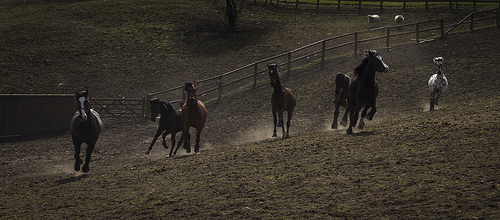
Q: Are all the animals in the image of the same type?
A: No, they are sheep and horses.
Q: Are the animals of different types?
A: Yes, they are sheep and horses.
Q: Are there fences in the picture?
A: Yes, there is a fence.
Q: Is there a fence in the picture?
A: Yes, there is a fence.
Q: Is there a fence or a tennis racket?
A: Yes, there is a fence.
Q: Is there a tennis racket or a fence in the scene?
A: Yes, there is a fence.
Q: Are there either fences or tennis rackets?
A: Yes, there is a fence.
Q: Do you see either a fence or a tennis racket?
A: Yes, there is a fence.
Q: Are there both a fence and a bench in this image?
A: No, there is a fence but no benches.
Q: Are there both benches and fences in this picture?
A: No, there is a fence but no benches.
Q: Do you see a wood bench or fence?
A: Yes, there is a wood fence.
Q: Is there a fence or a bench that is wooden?
A: Yes, the fence is wooden.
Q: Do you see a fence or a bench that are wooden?
A: Yes, the fence is wooden.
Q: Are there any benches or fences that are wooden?
A: Yes, the fence is wooden.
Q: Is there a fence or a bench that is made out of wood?
A: Yes, the fence is made of wood.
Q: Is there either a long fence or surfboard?
A: Yes, there is a long fence.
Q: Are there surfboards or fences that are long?
A: Yes, the fence is long.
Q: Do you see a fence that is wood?
A: Yes, there is a wood fence.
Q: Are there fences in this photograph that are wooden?
A: Yes, there is a fence that is wooden.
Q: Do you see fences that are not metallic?
A: Yes, there is a wooden fence.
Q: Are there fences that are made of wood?
A: Yes, there is a fence that is made of wood.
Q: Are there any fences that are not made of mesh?
A: Yes, there is a fence that is made of wood.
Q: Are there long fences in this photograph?
A: Yes, there is a long fence.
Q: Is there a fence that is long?
A: Yes, there is a fence that is long.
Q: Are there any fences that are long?
A: Yes, there is a fence that is long.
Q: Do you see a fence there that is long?
A: Yes, there is a fence that is long.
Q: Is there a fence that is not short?
A: Yes, there is a long fence.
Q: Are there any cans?
A: No, there are no cans.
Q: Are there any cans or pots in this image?
A: No, there are no cans or pots.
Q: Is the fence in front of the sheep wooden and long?
A: Yes, the fence is wooden and long.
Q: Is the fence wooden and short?
A: No, the fence is wooden but long.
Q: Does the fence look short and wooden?
A: No, the fence is wooden but long.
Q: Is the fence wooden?
A: Yes, the fence is wooden.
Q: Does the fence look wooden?
A: Yes, the fence is wooden.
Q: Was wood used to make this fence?
A: Yes, the fence is made of wood.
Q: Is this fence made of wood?
A: Yes, the fence is made of wood.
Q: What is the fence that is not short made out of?
A: The fence is made of wood.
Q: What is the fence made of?
A: The fence is made of wood.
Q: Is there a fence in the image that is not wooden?
A: No, there is a fence but it is wooden.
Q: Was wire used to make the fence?
A: No, the fence is made of wood.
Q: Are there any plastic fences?
A: No, there is a fence but it is made of wood.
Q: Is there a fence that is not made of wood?
A: No, there is a fence but it is made of wood.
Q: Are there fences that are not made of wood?
A: No, there is a fence but it is made of wood.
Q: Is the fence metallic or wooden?
A: The fence is wooden.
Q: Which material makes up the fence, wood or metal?
A: The fence is made of wood.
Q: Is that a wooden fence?
A: Yes, that is a wooden fence.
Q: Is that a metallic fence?
A: No, that is a wooden fence.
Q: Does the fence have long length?
A: Yes, the fence is long.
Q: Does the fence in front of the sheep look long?
A: Yes, the fence is long.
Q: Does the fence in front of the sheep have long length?
A: Yes, the fence is long.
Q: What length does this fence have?
A: The fence has long length.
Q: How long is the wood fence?
A: The fence is long.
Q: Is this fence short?
A: No, the fence is long.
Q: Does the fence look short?
A: No, the fence is long.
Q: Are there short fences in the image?
A: No, there is a fence but it is long.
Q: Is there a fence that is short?
A: No, there is a fence but it is long.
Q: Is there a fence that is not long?
A: No, there is a fence but it is long.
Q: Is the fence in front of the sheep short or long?
A: The fence is long.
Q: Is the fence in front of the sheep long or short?
A: The fence is long.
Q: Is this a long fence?
A: Yes, this is a long fence.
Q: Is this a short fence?
A: No, this is a long fence.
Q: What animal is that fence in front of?
A: The fence is in front of the sheep.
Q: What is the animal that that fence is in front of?
A: The animal is a sheep.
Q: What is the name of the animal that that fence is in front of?
A: The animal is a sheep.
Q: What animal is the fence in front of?
A: The fence is in front of the sheep.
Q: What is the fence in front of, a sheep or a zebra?
A: The fence is in front of a sheep.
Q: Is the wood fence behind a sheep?
A: No, the fence is in front of a sheep.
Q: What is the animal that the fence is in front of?
A: The animal is a sheep.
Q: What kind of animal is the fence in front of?
A: The fence is in front of the sheep.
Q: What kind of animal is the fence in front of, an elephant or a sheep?
A: The fence is in front of a sheep.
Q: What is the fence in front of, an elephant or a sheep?
A: The fence is in front of a sheep.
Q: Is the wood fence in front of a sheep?
A: Yes, the fence is in front of a sheep.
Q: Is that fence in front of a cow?
A: No, the fence is in front of a sheep.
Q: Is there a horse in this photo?
A: Yes, there is a horse.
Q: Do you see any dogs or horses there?
A: Yes, there is a horse.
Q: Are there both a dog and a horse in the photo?
A: No, there is a horse but no dogs.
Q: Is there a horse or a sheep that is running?
A: Yes, the horse is running.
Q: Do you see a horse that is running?
A: Yes, there is a horse that is running.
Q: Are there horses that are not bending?
A: Yes, there is a horse that is running.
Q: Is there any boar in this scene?
A: No, there are no boars.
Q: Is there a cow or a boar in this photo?
A: No, there are no boars or cows.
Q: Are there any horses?
A: Yes, there is a horse.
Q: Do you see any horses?
A: Yes, there is a horse.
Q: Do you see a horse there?
A: Yes, there is a horse.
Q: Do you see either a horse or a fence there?
A: Yes, there is a horse.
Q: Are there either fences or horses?
A: Yes, there is a horse.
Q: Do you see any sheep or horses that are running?
A: Yes, the horse is running.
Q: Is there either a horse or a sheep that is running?
A: Yes, the horse is running.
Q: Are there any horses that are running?
A: Yes, there is a horse that is running.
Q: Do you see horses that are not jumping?
A: Yes, there is a horse that is running .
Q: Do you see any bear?
A: No, there are no bears.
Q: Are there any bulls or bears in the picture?
A: No, there are no bears or bulls.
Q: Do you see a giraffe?
A: No, there are no giraffes.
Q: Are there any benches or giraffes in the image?
A: No, there are no giraffes or benches.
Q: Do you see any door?
A: Yes, there is a door.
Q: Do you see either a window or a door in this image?
A: Yes, there is a door.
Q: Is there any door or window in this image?
A: Yes, there is a door.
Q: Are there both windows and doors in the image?
A: No, there is a door but no windows.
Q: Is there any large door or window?
A: Yes, there is a large door.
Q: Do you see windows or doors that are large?
A: Yes, the door is large.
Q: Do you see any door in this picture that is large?
A: Yes, there is a large door.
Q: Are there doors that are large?
A: Yes, there is a door that is large.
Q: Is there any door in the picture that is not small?
A: Yes, there is a large door.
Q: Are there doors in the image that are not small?
A: Yes, there is a large door.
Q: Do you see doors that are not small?
A: Yes, there is a large door.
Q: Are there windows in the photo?
A: No, there are no windows.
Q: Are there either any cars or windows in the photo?
A: No, there are no windows or cars.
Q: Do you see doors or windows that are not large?
A: No, there is a door but it is large.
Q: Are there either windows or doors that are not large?
A: No, there is a door but it is large.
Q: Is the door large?
A: Yes, the door is large.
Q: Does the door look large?
A: Yes, the door is large.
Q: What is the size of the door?
A: The door is large.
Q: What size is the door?
A: The door is large.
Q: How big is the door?
A: The door is large.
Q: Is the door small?
A: No, the door is large.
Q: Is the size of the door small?
A: No, the door is large.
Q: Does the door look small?
A: No, the door is large.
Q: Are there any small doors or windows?
A: No, there is a door but it is large.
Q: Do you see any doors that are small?
A: No, there is a door but it is large.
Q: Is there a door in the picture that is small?
A: No, there is a door but it is large.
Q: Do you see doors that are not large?
A: No, there is a door but it is large.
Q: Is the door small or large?
A: The door is large.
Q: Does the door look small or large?
A: The door is large.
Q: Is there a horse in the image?
A: Yes, there is a horse.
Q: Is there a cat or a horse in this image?
A: Yes, there is a horse.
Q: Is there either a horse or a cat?
A: Yes, there is a horse.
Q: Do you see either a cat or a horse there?
A: Yes, there is a horse.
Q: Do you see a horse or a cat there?
A: Yes, there is a horse.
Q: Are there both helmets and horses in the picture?
A: No, there is a horse but no helmets.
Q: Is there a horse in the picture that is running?
A: Yes, there is a horse that is running.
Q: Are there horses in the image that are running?
A: Yes, there is a horse that is running.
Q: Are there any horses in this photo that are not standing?
A: Yes, there is a horse that is running.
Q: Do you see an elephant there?
A: No, there are no elephants.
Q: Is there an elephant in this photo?
A: No, there are no elephants.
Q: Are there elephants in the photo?
A: No, there are no elephants.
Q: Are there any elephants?
A: No, there are no elephants.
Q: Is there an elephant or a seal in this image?
A: No, there are no elephants or seals.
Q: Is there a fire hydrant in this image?
A: No, there are no fire hydrants.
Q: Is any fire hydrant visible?
A: No, there are no fire hydrants.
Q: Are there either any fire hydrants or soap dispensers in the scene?
A: No, there are no fire hydrants or soap dispensers.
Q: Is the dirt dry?
A: Yes, the dirt is dry.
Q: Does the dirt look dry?
A: Yes, the dirt is dry.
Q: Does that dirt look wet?
A: No, the dirt is dry.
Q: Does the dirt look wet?
A: No, the dirt is dry.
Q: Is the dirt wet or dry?
A: The dirt is dry.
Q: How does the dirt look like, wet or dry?
A: The dirt is dry.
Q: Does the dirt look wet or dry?
A: The dirt is dry.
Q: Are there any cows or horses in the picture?
A: Yes, there is a horse.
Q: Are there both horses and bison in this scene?
A: No, there is a horse but no bison.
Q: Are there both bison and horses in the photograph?
A: No, there is a horse but no bison.